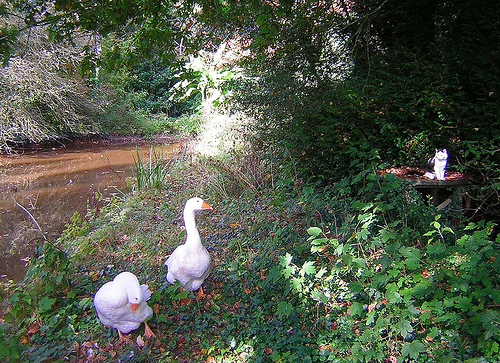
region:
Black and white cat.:
[405, 146, 449, 186]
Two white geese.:
[87, 196, 216, 345]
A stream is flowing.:
[2, 134, 213, 292]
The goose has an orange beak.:
[202, 198, 217, 213]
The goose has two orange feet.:
[116, 321, 161, 348]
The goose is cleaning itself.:
[92, 272, 159, 345]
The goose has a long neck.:
[183, 211, 202, 246]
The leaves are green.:
[360, 219, 411, 267]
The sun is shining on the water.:
[3, 143, 193, 208]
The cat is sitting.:
[403, 143, 449, 179]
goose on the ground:
[161, 185, 218, 300]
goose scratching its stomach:
[85, 268, 167, 349]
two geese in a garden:
[87, 178, 234, 347]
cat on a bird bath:
[421, 141, 448, 179]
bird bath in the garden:
[396, 163, 479, 205]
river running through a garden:
[0, 125, 200, 277]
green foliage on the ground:
[315, 211, 493, 362]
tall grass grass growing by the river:
[122, 143, 187, 200]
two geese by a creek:
[85, 187, 222, 345]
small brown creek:
[1, 137, 203, 286]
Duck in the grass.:
[157, 190, 228, 307]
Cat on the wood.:
[422, 139, 450, 181]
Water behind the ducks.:
[0, 128, 193, 308]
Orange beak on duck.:
[195, 194, 217, 214]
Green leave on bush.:
[275, 248, 295, 268]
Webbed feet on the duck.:
[105, 321, 161, 346]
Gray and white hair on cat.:
[416, 143, 450, 180]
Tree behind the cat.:
[181, 1, 496, 187]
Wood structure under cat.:
[379, 160, 467, 225]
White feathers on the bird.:
[157, 186, 229, 311]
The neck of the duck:
[178, 212, 203, 244]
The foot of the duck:
[134, 320, 161, 338]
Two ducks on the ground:
[91, 190, 231, 351]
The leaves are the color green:
[333, 234, 471, 348]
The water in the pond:
[18, 153, 102, 225]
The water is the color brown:
[10, 148, 103, 211]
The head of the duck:
[174, 185, 216, 214]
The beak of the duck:
[200, 198, 216, 217]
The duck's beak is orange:
[200, 196, 217, 214]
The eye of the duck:
[192, 195, 202, 208]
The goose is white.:
[160, 189, 217, 302]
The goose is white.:
[84, 266, 161, 347]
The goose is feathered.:
[151, 182, 222, 307]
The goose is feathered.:
[80, 260, 161, 347]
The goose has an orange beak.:
[155, 179, 227, 316]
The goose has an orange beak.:
[86, 266, 162, 356]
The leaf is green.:
[35, 288, 58, 316]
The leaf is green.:
[6, 285, 25, 309]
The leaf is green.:
[273, 296, 293, 325]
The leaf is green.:
[391, 313, 420, 342]